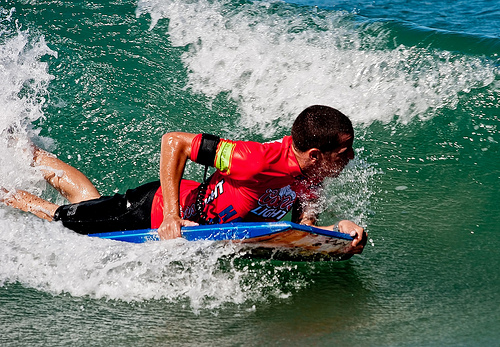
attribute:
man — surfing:
[4, 100, 356, 226]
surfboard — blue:
[90, 223, 360, 258]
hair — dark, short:
[285, 104, 358, 144]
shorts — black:
[53, 167, 161, 238]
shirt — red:
[148, 127, 312, 233]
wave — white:
[170, 12, 489, 121]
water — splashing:
[5, 40, 65, 289]